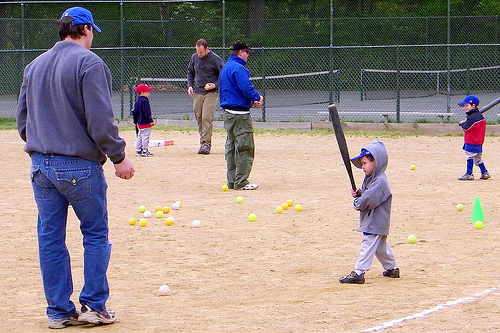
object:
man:
[13, 0, 138, 331]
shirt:
[13, 37, 130, 167]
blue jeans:
[27, 148, 115, 320]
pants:
[223, 109, 255, 190]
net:
[0, 46, 500, 124]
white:
[357, 284, 500, 333]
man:
[184, 36, 227, 155]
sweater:
[186, 50, 226, 95]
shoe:
[74, 302, 122, 325]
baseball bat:
[326, 102, 357, 191]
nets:
[357, 79, 369, 87]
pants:
[354, 232, 397, 272]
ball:
[248, 213, 257, 222]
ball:
[406, 234, 417, 245]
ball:
[156, 283, 171, 296]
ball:
[127, 217, 137, 227]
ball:
[235, 195, 245, 204]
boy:
[337, 140, 402, 285]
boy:
[455, 93, 493, 182]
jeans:
[27, 150, 114, 323]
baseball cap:
[57, 5, 103, 35]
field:
[0, 123, 500, 333]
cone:
[469, 195, 486, 225]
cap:
[457, 94, 480, 107]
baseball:
[191, 219, 202, 227]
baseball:
[171, 202, 181, 210]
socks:
[466, 158, 474, 175]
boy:
[129, 81, 158, 158]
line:
[353, 284, 500, 333]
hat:
[349, 147, 374, 169]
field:
[0, 50, 500, 126]